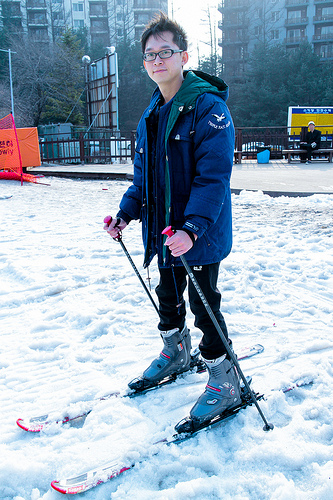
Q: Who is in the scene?
A: A man.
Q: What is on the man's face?
A: Glasses.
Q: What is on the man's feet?
A: Skis.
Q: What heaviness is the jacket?
A: Relatively.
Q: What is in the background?
A: Buildings.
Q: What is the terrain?
A: Snow.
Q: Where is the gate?
A: Background.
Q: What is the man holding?
A: Poles.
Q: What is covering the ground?
A: Snow.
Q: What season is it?
A: Winter.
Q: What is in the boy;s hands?
A: Ski poles.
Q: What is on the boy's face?
A: Glasses.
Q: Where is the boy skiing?
A: In the city.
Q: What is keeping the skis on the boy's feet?
A: Boots and binders.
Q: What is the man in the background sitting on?
A: A bench.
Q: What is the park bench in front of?
A: A fence.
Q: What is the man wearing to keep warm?
A: A blue coat.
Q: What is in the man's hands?
A: Poles.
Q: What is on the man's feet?
A: Boots.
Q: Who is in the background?
A: A person.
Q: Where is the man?
A: The man is outside.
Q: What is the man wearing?
A: Skis.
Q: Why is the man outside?
A: He is going skiing.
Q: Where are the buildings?
A: The buildings are in the background.